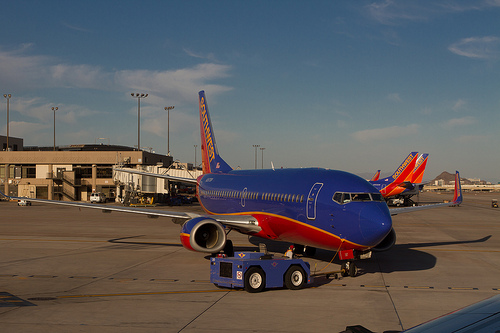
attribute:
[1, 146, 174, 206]
building — beige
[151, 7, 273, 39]
sky — blue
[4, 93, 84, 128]
cloud — white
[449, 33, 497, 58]
cloud — white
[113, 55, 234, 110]
cloud — white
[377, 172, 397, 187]
american flag — not towed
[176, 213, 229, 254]
engine — towed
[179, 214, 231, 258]
engine — red, orange, blue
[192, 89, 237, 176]
tail — red, blue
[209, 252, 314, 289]
cart — driven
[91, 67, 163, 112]
clouds — white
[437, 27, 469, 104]
clouds — white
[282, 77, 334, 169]
sky — blue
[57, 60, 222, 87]
clouds — white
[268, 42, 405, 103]
sky — blue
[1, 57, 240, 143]
cloud — white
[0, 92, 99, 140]
cloud — white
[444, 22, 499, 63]
cloud — white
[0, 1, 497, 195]
sky — blue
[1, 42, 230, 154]
clouds — white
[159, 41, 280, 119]
clouds — white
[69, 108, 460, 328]
airplane — blue, red, orange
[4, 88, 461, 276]
plane — blue, red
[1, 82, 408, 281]
plane — blue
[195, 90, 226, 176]
tail wing — pulled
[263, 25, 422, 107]
sky — blue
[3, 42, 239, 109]
clouds — white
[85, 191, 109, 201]
white van — white 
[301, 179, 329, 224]
door — blue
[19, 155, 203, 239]
wings — silver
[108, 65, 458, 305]
plane — blue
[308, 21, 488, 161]
cloud — white